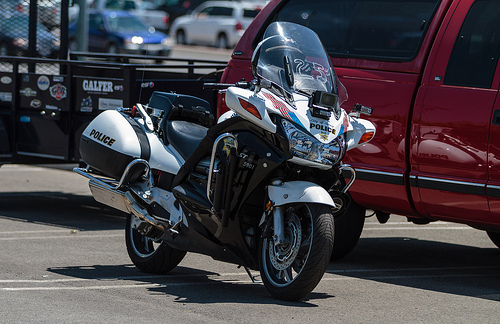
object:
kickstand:
[238, 262, 263, 282]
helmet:
[261, 37, 306, 71]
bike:
[76, 21, 374, 300]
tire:
[124, 200, 191, 273]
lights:
[308, 90, 338, 109]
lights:
[238, 97, 262, 120]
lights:
[358, 131, 375, 145]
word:
[89, 129, 116, 147]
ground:
[318, 195, 492, 324]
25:
[292, 58, 328, 83]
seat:
[163, 117, 224, 160]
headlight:
[282, 118, 341, 169]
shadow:
[337, 237, 500, 305]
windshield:
[256, 21, 336, 99]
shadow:
[0, 185, 125, 230]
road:
[2, 160, 499, 322]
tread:
[314, 225, 334, 273]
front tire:
[254, 179, 334, 302]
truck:
[213, 1, 500, 252]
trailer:
[24, 25, 225, 189]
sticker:
[97, 99, 123, 112]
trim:
[368, 161, 489, 198]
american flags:
[260, 91, 305, 129]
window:
[256, 0, 440, 59]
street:
[46, 228, 241, 319]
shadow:
[68, 245, 275, 297]